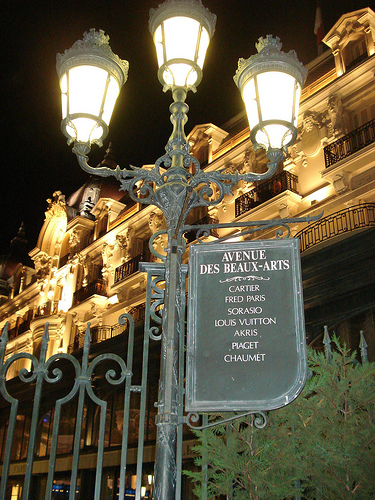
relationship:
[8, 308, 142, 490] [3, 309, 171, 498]
metal rails on fence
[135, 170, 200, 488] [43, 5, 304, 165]
pole has lights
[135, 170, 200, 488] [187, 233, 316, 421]
pole has sign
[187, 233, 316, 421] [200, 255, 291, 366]
sign has words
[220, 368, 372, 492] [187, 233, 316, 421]
bush behind sign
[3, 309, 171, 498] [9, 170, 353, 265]
fence in front of building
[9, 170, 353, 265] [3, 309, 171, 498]
building behind fence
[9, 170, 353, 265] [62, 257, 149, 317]
building has balcony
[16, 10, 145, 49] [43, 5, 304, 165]
sky behind lights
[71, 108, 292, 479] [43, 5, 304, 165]
lamp post has lights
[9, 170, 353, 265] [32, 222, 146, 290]
building has details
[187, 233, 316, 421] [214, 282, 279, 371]
sign has names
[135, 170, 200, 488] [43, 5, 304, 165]
pole under lamps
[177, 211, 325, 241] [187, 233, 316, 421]
bar holding sign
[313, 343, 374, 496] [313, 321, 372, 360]
tree in front of fence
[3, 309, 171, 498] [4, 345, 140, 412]
fence has curly metal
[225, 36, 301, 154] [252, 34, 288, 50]
lamp has crown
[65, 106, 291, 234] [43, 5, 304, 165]
lamppost has three lights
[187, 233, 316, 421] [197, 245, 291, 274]
sign naming avenue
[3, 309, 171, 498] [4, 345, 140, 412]
gate has metal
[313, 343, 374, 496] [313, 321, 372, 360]
branches are covering fence